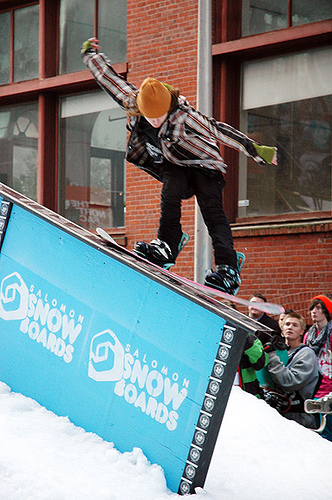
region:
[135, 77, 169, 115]
the beanie is orange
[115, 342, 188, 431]
white lettering on the sign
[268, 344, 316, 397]
a gray sweater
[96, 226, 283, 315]
a snow board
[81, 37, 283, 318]
the man is snowboarding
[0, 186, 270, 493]
a trick rail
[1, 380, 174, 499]
snow on the ground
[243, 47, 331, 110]
the window curtain is open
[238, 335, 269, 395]
green and black stripes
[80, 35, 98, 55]
gloves on the person's hand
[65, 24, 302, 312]
boy snowboarding on ramp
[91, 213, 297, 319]
snowboard on ramp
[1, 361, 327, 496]
snow covered hill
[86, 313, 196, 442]
snowboard brand name on front of blue sign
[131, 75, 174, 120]
dark orange hat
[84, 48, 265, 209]
striped jacket with hood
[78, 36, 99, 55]
green fingerless gloves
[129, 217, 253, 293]
teal and black snowboard shoes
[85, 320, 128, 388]
white logo on front of sign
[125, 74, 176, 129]
head of a person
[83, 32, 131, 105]
arm of a person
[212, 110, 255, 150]
arm of a person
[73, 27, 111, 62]
hand of a person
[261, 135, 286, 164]
hand of a person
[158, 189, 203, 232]
leg of a person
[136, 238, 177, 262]
feet of a person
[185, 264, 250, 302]
feet of a person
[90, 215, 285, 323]
person snow boarding on a ramp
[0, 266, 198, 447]
Logo on the side of a snow board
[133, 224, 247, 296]
person wearing black boots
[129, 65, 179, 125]
man wearing a brown hat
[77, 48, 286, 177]
man wearing a striped shirt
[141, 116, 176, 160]
man wearing a black shirt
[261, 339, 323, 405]
man wearing a gray shirt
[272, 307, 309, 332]
man with blonde hair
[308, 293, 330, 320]
man wearing a red hat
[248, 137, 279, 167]
man wearing green gloves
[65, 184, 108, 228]
reflection of a red sign in the window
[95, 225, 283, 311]
black snowboard with red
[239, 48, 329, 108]
white blind in the window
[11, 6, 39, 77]
window pane on the top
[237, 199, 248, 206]
white sticker on the window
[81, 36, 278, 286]
kid on a snowboard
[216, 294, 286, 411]
person in green and black striped shirt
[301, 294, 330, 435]
kid in a pink shirt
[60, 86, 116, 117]
white blind in the window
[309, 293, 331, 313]
orange head warmer